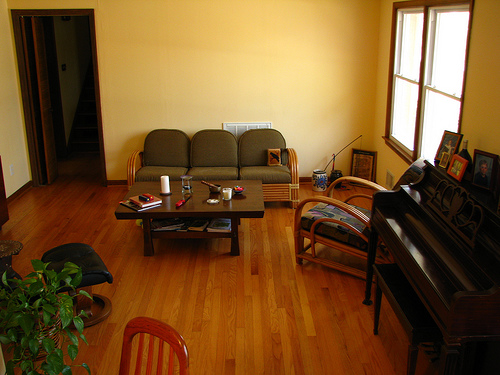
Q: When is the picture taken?
A: Daytime.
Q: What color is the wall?
A: Yellow.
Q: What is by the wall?
A: Couch.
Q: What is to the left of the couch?
A: Door.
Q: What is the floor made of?
A: Wood.